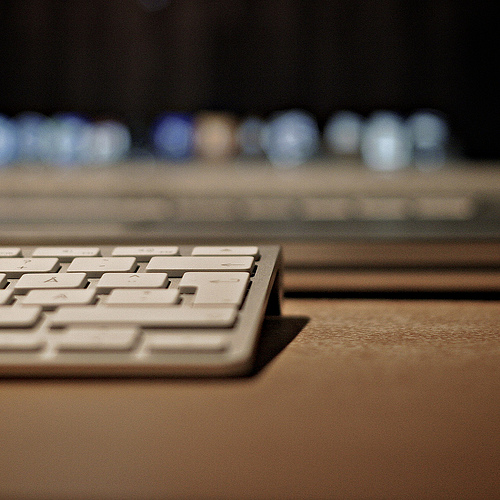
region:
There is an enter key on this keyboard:
[200, 268, 260, 342]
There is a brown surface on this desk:
[378, 336, 428, 411]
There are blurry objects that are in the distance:
[316, 91, 403, 202]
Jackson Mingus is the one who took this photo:
[67, 96, 342, 403]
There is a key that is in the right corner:
[203, 246, 276, 309]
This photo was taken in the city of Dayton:
[93, 143, 383, 498]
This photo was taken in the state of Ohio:
[104, 151, 403, 482]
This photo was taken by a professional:
[100, 192, 351, 468]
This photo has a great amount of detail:
[138, 173, 419, 488]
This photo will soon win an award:
[101, 165, 381, 477]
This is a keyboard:
[0, 237, 494, 372]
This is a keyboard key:
[142, 318, 252, 353]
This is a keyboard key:
[41, 325, 157, 361]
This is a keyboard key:
[46, 300, 242, 326]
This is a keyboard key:
[176, 270, 253, 305]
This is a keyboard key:
[97, 268, 168, 287]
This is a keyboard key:
[144, 251, 263, 278]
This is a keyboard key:
[187, 231, 271, 265]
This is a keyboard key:
[27, 240, 104, 265]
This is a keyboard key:
[22, 278, 99, 318]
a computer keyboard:
[1, 230, 282, 381]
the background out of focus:
[4, 94, 496, 201]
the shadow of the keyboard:
[264, 313, 311, 375]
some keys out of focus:
[3, 307, 225, 362]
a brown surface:
[308, 383, 490, 496]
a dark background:
[4, 11, 497, 93]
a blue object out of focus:
[158, 117, 188, 158]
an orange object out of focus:
[193, 118, 233, 158]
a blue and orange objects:
[156, 112, 233, 159]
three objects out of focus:
[331, 116, 449, 168]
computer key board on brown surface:
[20, 237, 290, 372]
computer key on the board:
[195, 241, 258, 258]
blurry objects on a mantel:
[315, 102, 445, 177]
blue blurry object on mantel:
[150, 112, 190, 162]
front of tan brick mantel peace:
[312, 175, 457, 230]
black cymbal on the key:
[22, 273, 87, 292]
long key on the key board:
[147, 254, 257, 276]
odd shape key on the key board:
[176, 270, 253, 309]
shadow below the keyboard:
[242, 288, 305, 411]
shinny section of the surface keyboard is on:
[301, 293, 459, 396]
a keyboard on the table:
[0, 233, 280, 379]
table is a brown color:
[22, 236, 496, 481]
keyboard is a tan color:
[5, 241, 243, 355]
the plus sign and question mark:
[8, 252, 52, 270]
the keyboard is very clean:
[7, 240, 263, 355]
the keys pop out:
[0, 235, 280, 346]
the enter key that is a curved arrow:
[195, 272, 245, 304]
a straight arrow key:
[148, 256, 255, 270]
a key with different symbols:
[101, 270, 164, 290]